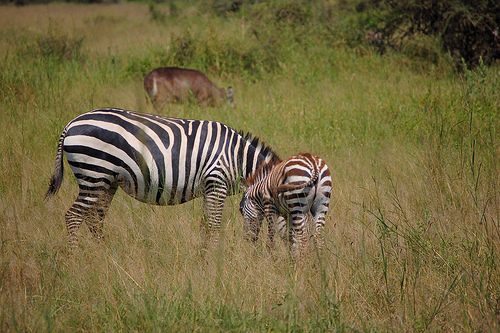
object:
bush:
[0, 15, 286, 66]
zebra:
[238, 152, 334, 271]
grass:
[1, 257, 254, 333]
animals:
[142, 66, 236, 113]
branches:
[369, 0, 499, 68]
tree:
[373, 1, 500, 62]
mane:
[238, 126, 284, 163]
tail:
[41, 130, 65, 207]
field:
[286, 60, 380, 132]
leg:
[64, 176, 115, 249]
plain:
[0, 0, 500, 333]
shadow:
[455, 35, 499, 64]